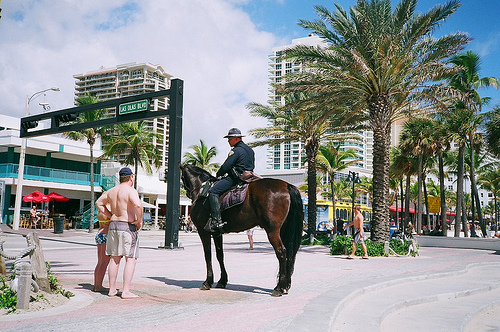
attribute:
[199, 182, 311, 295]
horse — brown, black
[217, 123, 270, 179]
officer — close, white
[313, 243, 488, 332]
street — close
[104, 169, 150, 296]
man — standing, shirtless, white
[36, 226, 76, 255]
road — paved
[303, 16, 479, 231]
tree — black, green, palm, brown, plam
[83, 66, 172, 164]
building — close, large, big, white, tall, huge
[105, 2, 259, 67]
sky — blue, cloudy, white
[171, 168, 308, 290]
horse — brown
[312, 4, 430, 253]
tree — palm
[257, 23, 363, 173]
building — tall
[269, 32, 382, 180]
building — tall, multi story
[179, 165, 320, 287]
horse — brown, beautiful